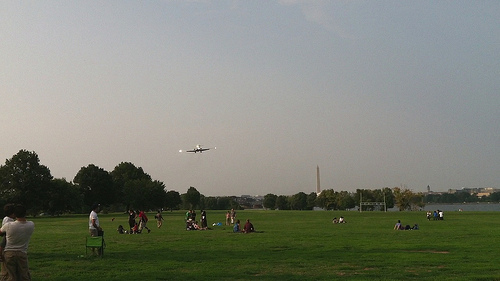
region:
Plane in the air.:
[142, 103, 262, 180]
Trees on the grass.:
[61, 129, 223, 266]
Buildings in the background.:
[287, 128, 496, 228]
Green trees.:
[57, 149, 219, 244]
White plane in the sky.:
[155, 116, 265, 186]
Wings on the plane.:
[157, 127, 262, 177]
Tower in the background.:
[279, 152, 371, 210]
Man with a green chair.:
[70, 206, 113, 276]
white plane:
[182, 133, 212, 163]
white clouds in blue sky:
[24, 17, 66, 55]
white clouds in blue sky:
[394, 34, 424, 64]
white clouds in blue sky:
[379, 55, 417, 104]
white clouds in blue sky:
[363, 81, 398, 121]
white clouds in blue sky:
[183, 42, 218, 97]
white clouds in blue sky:
[254, 99, 277, 124]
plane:
[177, 133, 237, 169]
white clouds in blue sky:
[44, 26, 92, 55]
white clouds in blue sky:
[373, 68, 409, 115]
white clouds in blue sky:
[417, 25, 458, 68]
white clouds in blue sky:
[317, 53, 359, 98]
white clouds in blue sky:
[388, 105, 426, 146]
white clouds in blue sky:
[281, 48, 332, 90]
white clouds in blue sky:
[176, 17, 240, 75]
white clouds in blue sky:
[131, 13, 163, 45]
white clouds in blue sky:
[61, 49, 105, 72]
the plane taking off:
[176, 132, 220, 164]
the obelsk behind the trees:
[312, 158, 323, 195]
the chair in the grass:
[82, 230, 108, 260]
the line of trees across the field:
[263, 187, 359, 211]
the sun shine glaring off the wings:
[177, 147, 187, 156]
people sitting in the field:
[228, 215, 268, 232]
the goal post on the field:
[354, 187, 391, 216]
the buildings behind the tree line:
[407, 179, 499, 198]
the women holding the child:
[0, 198, 41, 275]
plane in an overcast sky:
[177, 138, 222, 157]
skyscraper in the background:
[311, 157, 325, 201]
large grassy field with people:
[0, 203, 498, 279]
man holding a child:
[0, 203, 37, 280]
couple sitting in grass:
[230, 218, 259, 233]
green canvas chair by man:
[83, 230, 107, 257]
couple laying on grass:
[391, 217, 421, 234]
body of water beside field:
[317, 194, 498, 216]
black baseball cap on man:
[89, 198, 103, 211]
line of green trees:
[2, 148, 187, 211]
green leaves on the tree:
[95, 186, 109, 192]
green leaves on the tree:
[141, 187, 153, 197]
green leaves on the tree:
[116, 161, 135, 175]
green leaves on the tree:
[103, 178, 120, 201]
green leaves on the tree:
[76, 187, 82, 197]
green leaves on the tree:
[53, 203, 77, 215]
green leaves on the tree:
[41, 173, 58, 194]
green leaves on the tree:
[24, 146, 49, 176]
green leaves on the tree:
[3, 170, 150, 275]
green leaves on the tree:
[288, 199, 295, 207]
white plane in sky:
[178, 142, 215, 154]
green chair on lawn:
[84, 232, 106, 254]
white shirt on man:
[87, 210, 97, 229]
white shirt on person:
[3, 220, 33, 251]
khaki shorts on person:
[4, 249, 32, 279]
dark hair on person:
[12, 203, 24, 216]